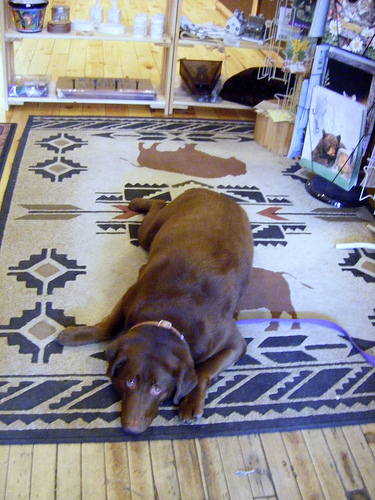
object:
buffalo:
[137, 142, 247, 178]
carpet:
[0, 114, 375, 447]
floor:
[56, 75, 155, 99]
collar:
[128, 319, 172, 329]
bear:
[311, 129, 346, 167]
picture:
[299, 85, 368, 193]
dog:
[55, 188, 254, 436]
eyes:
[124, 379, 135, 389]